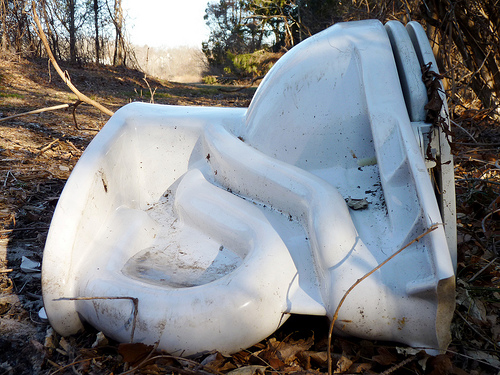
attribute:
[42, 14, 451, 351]
toilet — white, broken, old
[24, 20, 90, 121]
stick — brown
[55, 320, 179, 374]
branch — brown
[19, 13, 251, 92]
woods — brown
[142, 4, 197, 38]
sky — clear, blue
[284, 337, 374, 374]
leaves — brown, dirty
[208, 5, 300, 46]
trees — green, tall